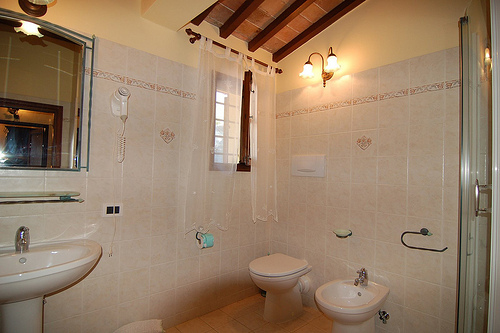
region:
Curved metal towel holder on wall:
[398, 216, 455, 264]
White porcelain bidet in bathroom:
[315, 263, 396, 330]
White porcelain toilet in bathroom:
[245, 247, 314, 331]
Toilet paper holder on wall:
[194, 227, 225, 252]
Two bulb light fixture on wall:
[295, 43, 347, 93]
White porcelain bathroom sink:
[0, 228, 105, 331]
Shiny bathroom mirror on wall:
[0, 14, 92, 170]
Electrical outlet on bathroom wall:
[100, 199, 127, 219]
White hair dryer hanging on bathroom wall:
[112, 84, 135, 170]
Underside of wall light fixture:
[10, 0, 52, 20]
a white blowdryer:
[105, 83, 132, 165]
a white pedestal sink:
[2, 232, 104, 331]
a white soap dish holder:
[329, 225, 356, 240]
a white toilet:
[245, 251, 312, 327]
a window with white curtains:
[176, 42, 285, 229]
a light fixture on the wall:
[300, 47, 345, 93]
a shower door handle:
[468, 175, 490, 215]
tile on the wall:
[341, 82, 442, 178]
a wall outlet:
[97, 199, 125, 220]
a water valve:
[375, 306, 392, 325]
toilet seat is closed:
[223, 231, 313, 301]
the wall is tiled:
[129, 134, 184, 304]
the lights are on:
[288, 39, 368, 107]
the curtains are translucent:
[171, 17, 303, 225]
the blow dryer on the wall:
[95, 77, 178, 195]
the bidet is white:
[313, 247, 383, 329]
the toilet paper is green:
[188, 225, 248, 262]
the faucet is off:
[10, 222, 37, 263]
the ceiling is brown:
[206, 7, 320, 88]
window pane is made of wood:
[194, 57, 288, 180]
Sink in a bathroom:
[0, 221, 109, 330]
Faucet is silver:
[10, 221, 35, 257]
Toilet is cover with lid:
[243, 238, 315, 327]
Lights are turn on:
[293, 42, 346, 97]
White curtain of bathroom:
[248, 61, 285, 225]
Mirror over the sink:
[1, 3, 101, 178]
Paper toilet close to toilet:
[187, 219, 219, 253]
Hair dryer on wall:
[106, 76, 135, 169]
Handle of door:
[468, 175, 498, 220]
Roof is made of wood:
[191, 1, 378, 65]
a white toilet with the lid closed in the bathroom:
[235, 241, 314, 322]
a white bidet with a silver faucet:
[314, 267, 395, 332]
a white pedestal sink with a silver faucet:
[4, 217, 114, 332]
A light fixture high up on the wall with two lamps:
[293, 44, 349, 94]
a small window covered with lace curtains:
[202, 61, 277, 182]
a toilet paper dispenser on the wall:
[193, 224, 216, 255]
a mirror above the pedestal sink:
[1, 4, 98, 186]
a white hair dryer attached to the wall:
[108, 76, 137, 176]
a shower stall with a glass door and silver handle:
[454, 17, 499, 332]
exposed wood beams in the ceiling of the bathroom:
[210, 3, 339, 60]